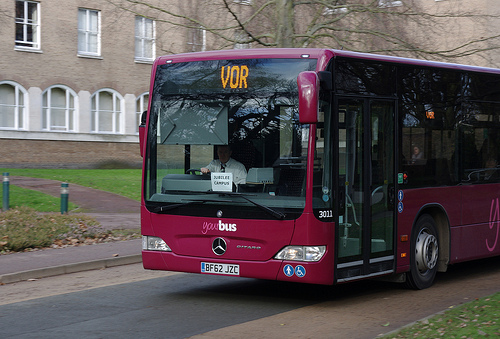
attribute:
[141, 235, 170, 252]
light — white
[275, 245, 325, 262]
light — white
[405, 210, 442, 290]
wheel — black, big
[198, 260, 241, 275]
license plate — blue, white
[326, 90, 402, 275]
bus door — large, red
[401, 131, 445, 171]
ground — glass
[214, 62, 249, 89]
sign — orange, lighted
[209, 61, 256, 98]
bus sign — orange, black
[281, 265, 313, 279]
stickers — round, blue, white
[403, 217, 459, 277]
tire — black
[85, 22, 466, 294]
bus — big 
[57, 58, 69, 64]
brick — tan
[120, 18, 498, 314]
bus — purple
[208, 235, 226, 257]
logo — black, silver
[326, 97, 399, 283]
doors — black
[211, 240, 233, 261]
logo — round